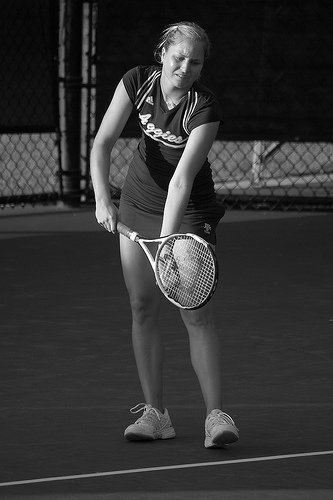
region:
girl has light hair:
[156, 18, 216, 62]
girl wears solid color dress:
[118, 69, 230, 232]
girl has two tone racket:
[135, 230, 225, 308]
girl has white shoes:
[126, 384, 266, 453]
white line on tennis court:
[15, 436, 308, 487]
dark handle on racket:
[101, 210, 150, 252]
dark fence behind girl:
[117, 26, 300, 187]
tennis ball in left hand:
[150, 238, 190, 306]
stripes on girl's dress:
[120, 64, 211, 155]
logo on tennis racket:
[146, 233, 213, 307]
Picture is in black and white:
[11, 10, 325, 490]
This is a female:
[78, 18, 269, 427]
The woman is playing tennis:
[93, 24, 259, 472]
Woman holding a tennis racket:
[93, 190, 229, 314]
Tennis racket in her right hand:
[92, 196, 235, 323]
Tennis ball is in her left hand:
[155, 254, 187, 295]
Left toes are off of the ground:
[203, 400, 246, 457]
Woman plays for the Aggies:
[120, 114, 198, 160]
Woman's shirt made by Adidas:
[137, 80, 158, 109]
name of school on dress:
[132, 119, 187, 155]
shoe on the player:
[122, 402, 175, 448]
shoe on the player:
[196, 406, 244, 463]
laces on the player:
[128, 400, 162, 417]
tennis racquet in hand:
[142, 243, 211, 294]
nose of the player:
[179, 62, 190, 74]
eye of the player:
[186, 58, 201, 67]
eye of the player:
[170, 51, 182, 60]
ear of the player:
[159, 47, 164, 63]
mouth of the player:
[171, 71, 188, 80]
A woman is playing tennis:
[82, 15, 250, 454]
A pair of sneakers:
[118, 399, 242, 454]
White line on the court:
[1, 442, 331, 490]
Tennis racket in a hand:
[90, 202, 221, 317]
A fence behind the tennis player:
[1, 1, 331, 216]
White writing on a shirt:
[134, 106, 191, 149]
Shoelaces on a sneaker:
[124, 398, 164, 426]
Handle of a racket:
[111, 215, 138, 251]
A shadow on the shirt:
[139, 134, 217, 198]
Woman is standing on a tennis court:
[2, 1, 330, 498]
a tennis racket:
[118, 221, 216, 312]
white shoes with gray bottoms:
[123, 406, 239, 451]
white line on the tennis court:
[2, 448, 332, 494]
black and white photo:
[1, 2, 332, 495]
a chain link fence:
[4, 10, 331, 210]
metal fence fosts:
[49, 38, 96, 201]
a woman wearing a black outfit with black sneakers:
[112, 35, 242, 448]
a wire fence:
[8, 3, 328, 209]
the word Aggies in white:
[138, 111, 190, 148]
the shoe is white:
[119, 403, 176, 445]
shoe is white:
[200, 410, 241, 453]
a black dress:
[106, 69, 212, 242]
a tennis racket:
[109, 222, 226, 319]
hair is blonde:
[151, 20, 210, 57]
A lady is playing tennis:
[81, 13, 248, 453]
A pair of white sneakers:
[116, 394, 243, 453]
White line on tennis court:
[0, 438, 329, 492]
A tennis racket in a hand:
[85, 195, 225, 313]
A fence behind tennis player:
[0, 0, 327, 220]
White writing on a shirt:
[129, 101, 191, 150]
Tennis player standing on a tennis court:
[0, 0, 328, 494]